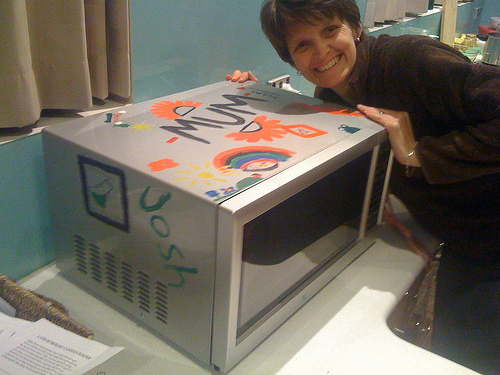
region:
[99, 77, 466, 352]
microwave n the table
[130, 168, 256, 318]
Josh written on side of microwave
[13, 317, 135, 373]
stack of papers on the table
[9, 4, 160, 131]
curtain on the window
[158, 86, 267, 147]
MUM written on top of microwave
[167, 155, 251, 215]
yellow sun on top of microwave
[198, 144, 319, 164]
rainbow on top of the microwave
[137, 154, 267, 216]
flowers on the top of microwave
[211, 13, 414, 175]
woman holding the microwave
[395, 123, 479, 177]
woman is wearing a bracelet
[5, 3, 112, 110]
Hanging tan curtains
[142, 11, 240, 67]
Blue painted wall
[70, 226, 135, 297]
Vents on side of microwave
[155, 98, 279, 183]
Art on top of microwave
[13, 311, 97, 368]
Paper laying on white table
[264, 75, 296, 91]
Stainless steel wall outlet cover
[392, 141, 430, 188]
Silver bracelet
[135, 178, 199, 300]
Name painted in green on side of microwave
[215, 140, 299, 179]
Rainbow painted on top of microwave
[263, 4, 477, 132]
Woman wearing brown coat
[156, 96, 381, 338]
Silver microwave decorated by children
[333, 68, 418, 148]
Woman's hand on microwave oven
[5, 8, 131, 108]
Beige curtain behind microwave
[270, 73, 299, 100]
White plug plugged into silver electrical outlet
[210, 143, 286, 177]
Rainbow painted on appliance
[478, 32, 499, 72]
Silver crockpot on counter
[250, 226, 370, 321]
Reflection of table in microwave door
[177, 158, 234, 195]
Sun drawn on appliance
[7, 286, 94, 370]
Literature stacked in a basket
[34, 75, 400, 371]
silver microwave with art on it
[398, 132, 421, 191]
silver bracelet on wrist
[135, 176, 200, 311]
Josh written in green paint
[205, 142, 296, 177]
rainbow painted on top of microwave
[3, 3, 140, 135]
beige curtain over window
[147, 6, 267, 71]
wall painted blue-green.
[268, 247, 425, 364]
white counter top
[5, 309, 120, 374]
sheet of paper with text on it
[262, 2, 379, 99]
woman with brown hair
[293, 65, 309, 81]
small gold hoop earring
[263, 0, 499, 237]
A woman in a brown sweater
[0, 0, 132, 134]
Some brown curtains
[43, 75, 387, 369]
A silver colored microwave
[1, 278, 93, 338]
A wicker basket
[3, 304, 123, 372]
some papers in a wicker basket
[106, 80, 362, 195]
some drawings on the microwave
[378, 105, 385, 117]
A ring on a woman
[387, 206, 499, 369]
A brown purse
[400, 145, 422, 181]
A bracelet on a woman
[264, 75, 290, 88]
An electrical outlet